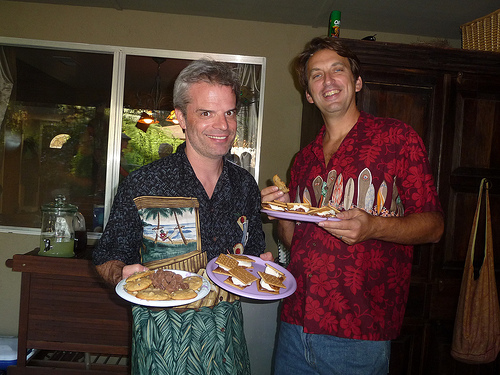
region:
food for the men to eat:
[103, 248, 312, 330]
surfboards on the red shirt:
[314, 167, 379, 221]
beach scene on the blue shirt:
[133, 193, 204, 256]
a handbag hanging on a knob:
[449, 165, 496, 371]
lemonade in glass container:
[28, 187, 85, 269]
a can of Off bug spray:
[323, 2, 353, 44]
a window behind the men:
[3, 27, 118, 244]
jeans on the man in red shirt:
[265, 312, 391, 373]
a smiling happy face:
[169, 53, 247, 167]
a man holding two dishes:
[99, 39, 300, 372]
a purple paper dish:
[201, 246, 302, 308]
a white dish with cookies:
[110, 258, 215, 313]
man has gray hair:
[132, 47, 283, 208]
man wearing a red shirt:
[250, 20, 459, 370]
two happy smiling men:
[127, 10, 433, 252]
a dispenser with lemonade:
[22, 180, 99, 269]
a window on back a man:
[0, 20, 290, 362]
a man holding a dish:
[245, 26, 452, 251]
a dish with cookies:
[201, 244, 302, 314]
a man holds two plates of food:
[87, 52, 310, 374]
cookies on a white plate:
[109, 261, 214, 313]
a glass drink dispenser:
[31, 195, 82, 260]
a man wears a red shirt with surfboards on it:
[266, 32, 453, 374]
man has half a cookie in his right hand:
[258, 31, 445, 267]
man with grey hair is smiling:
[171, 50, 249, 164]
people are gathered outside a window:
[108, 123, 260, 208]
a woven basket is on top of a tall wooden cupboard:
[453, 2, 498, 54]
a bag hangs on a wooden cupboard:
[443, 172, 498, 374]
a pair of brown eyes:
[190, 104, 239, 124]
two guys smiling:
[100, 26, 476, 373]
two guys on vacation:
[101, 24, 445, 374]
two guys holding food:
[82, 40, 453, 370]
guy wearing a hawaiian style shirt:
[91, 50, 302, 373]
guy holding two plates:
[90, 54, 315, 371]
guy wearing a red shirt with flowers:
[276, 40, 424, 362]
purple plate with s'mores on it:
[205, 244, 303, 311]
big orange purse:
[447, 166, 499, 373]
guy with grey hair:
[84, 53, 297, 373]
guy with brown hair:
[265, 42, 459, 373]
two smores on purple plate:
[262, 258, 314, 310]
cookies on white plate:
[134, 270, 206, 305]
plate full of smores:
[265, 193, 362, 243]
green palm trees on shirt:
[133, 184, 213, 242]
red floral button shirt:
[298, 246, 380, 317]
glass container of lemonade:
[26, 192, 85, 261]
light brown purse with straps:
[446, 134, 490, 374]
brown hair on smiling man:
[288, 36, 374, 113]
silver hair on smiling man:
[159, 27, 263, 172]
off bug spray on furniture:
[328, 8, 360, 49]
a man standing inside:
[298, 3, 418, 287]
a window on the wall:
[97, 29, 298, 273]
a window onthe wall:
[5, 43, 97, 243]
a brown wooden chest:
[352, 20, 492, 244]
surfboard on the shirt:
[342, 165, 363, 207]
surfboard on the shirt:
[371, 183, 391, 218]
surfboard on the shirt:
[301, 170, 326, 211]